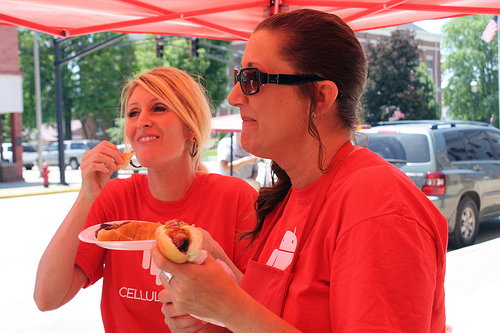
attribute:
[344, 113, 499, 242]
suv — grey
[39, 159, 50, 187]
fire hydrant — red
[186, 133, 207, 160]
earring — black, hooped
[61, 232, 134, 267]
plate — paper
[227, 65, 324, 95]
sunglasses — thick, black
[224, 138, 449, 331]
shirt — red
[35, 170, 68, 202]
fire hydrant — red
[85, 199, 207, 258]
disposable plate — white, round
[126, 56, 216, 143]
hair — blonde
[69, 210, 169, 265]
plate — white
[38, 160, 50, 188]
hydrant — red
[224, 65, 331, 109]
sunglasses — black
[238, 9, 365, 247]
hair — brown